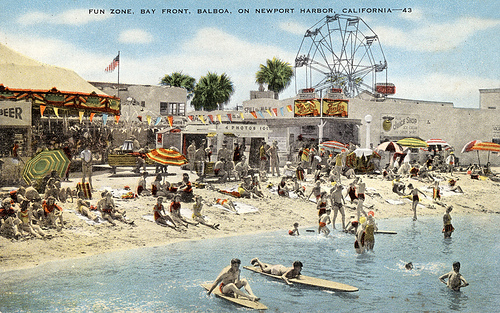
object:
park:
[0, 12, 500, 313]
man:
[250, 257, 303, 286]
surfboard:
[243, 263, 359, 292]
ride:
[295, 13, 387, 98]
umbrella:
[145, 148, 189, 166]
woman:
[352, 221, 366, 254]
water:
[1, 216, 500, 313]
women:
[153, 195, 220, 231]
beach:
[1, 161, 500, 270]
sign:
[379, 113, 419, 140]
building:
[0, 79, 499, 168]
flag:
[105, 55, 119, 73]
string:
[35, 103, 292, 129]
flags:
[35, 105, 294, 129]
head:
[405, 262, 413, 271]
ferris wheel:
[294, 13, 387, 99]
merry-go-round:
[0, 39, 121, 159]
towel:
[212, 202, 260, 213]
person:
[80, 144, 94, 189]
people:
[134, 169, 196, 199]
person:
[214, 197, 236, 211]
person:
[405, 262, 413, 270]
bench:
[108, 155, 156, 177]